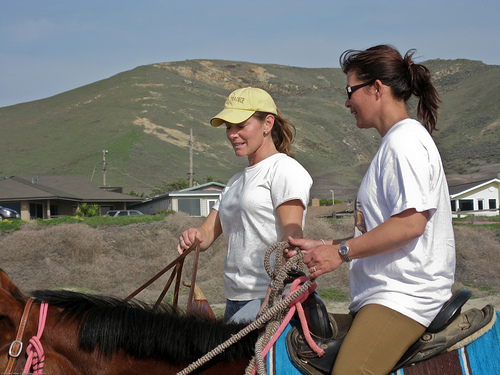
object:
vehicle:
[105, 210, 144, 218]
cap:
[209, 86, 278, 128]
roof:
[0, 173, 148, 200]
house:
[1, 173, 145, 219]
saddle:
[286, 288, 496, 374]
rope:
[173, 240, 316, 374]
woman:
[281, 42, 457, 374]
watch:
[338, 241, 351, 262]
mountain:
[0, 58, 498, 214]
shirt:
[346, 118, 456, 330]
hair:
[337, 42, 441, 135]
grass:
[0, 212, 166, 229]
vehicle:
[0, 207, 20, 218]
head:
[342, 45, 408, 129]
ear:
[374, 79, 383, 100]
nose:
[345, 96, 351, 107]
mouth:
[231, 141, 246, 149]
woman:
[176, 86, 312, 324]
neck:
[375, 101, 411, 137]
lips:
[350, 109, 359, 116]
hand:
[301, 244, 342, 278]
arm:
[191, 173, 240, 252]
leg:
[329, 296, 446, 374]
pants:
[330, 303, 428, 375]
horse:
[0, 270, 499, 374]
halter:
[176, 260, 191, 304]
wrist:
[338, 239, 352, 262]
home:
[447, 177, 499, 217]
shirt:
[212, 153, 313, 301]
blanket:
[261, 312, 499, 375]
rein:
[120, 236, 203, 314]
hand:
[177, 227, 204, 255]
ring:
[313, 265, 316, 271]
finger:
[309, 265, 321, 274]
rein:
[168, 240, 315, 374]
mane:
[27, 289, 260, 365]